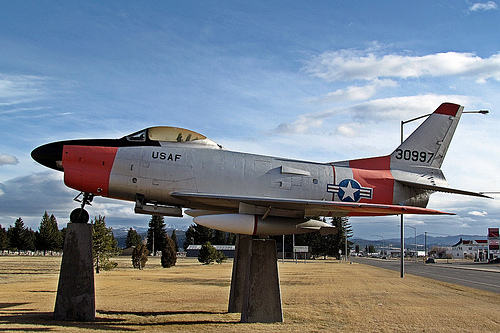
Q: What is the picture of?
A: A jet.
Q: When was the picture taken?
A: Daytime.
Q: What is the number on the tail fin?
A: 30997.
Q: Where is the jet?
A: On pedestals.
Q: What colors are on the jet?
A: Gray, red and black.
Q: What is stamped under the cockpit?
A: USAF.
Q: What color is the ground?
A: Tan.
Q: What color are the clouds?
A: White.